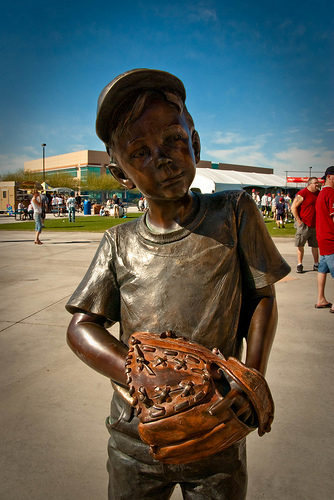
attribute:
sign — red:
[284, 176, 321, 185]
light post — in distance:
[40, 142, 46, 181]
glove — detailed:
[115, 323, 293, 470]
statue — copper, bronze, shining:
[64, 59, 293, 497]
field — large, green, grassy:
[1, 215, 296, 236]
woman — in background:
[28, 188, 48, 242]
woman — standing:
[26, 188, 48, 243]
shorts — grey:
[294, 220, 318, 249]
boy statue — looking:
[50, 31, 272, 318]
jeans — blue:
[76, 358, 283, 498]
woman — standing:
[13, 171, 61, 254]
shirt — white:
[29, 194, 43, 212]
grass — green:
[80, 225, 97, 237]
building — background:
[20, 149, 295, 207]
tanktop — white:
[29, 195, 39, 215]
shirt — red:
[294, 187, 318, 227]